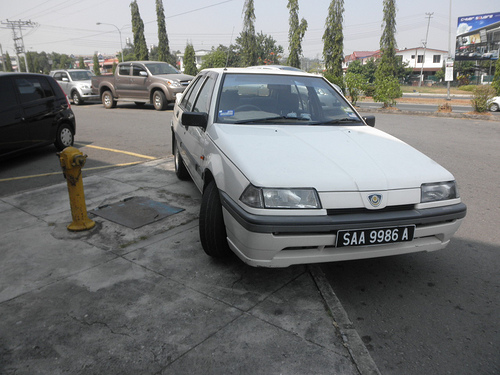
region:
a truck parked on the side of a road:
[95, 58, 199, 130]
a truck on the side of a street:
[89, 59, 191, 115]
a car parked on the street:
[42, 68, 94, 106]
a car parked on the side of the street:
[1, 63, 83, 168]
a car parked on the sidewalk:
[172, 55, 472, 287]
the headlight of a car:
[245, 180, 325, 208]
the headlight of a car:
[417, 180, 459, 206]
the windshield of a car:
[215, 68, 358, 133]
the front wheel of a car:
[191, 175, 236, 262]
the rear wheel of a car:
[167, 134, 186, 179]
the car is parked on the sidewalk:
[184, 160, 310, 325]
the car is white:
[273, 137, 306, 167]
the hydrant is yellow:
[51, 144, 94, 216]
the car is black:
[28, 113, 50, 137]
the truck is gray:
[118, 78, 141, 94]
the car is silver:
[62, 74, 86, 95]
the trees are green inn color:
[375, 45, 395, 86]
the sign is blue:
[462, 13, 480, 29]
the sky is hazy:
[191, 10, 221, 25]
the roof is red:
[356, 49, 370, 58]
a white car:
[138, 41, 481, 305]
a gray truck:
[78, 53, 234, 114]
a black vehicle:
[1, 64, 106, 164]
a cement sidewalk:
[24, 171, 250, 367]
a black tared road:
[391, 100, 496, 207]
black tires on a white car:
[148, 122, 245, 262]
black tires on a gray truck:
[64, 71, 198, 128]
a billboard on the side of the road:
[441, 7, 498, 78]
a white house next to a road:
[321, 36, 493, 113]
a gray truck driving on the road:
[62, 53, 237, 157]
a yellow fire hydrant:
[60, 147, 96, 234]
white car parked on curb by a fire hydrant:
[172, 66, 466, 272]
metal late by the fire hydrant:
[96, 193, 185, 228]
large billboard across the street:
[455, 12, 498, 59]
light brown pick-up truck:
[90, 58, 191, 110]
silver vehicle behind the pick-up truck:
[53, 69, 96, 102]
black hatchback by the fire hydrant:
[3, 71, 75, 164]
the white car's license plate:
[337, 224, 418, 244]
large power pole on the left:
[3, 18, 42, 70]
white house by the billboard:
[355, 48, 444, 82]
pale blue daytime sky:
[9, 2, 498, 53]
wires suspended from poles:
[8, 10, 452, 68]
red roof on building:
[350, 44, 450, 71]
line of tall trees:
[128, 0, 405, 90]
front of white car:
[178, 64, 465, 271]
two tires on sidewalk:
[169, 146, 320, 281]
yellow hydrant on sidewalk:
[58, 146, 95, 231]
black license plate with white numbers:
[338, 226, 413, 246]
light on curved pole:
[96, 22, 123, 57]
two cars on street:
[56, 59, 190, 102]